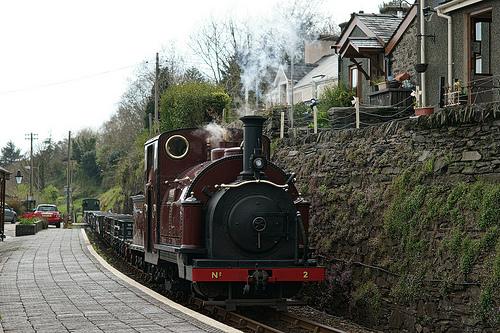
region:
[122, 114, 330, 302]
and old fashioned train engine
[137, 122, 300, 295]
the train is burgundy, black, and red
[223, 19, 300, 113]
white smoke billowing from train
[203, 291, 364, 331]
train tracks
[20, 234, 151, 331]
a stone pathway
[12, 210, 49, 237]
flowerboxes with red flowers in them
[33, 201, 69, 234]
the rear end of a red car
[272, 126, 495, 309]
a stone wall next to the train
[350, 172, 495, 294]
wall is covered in green vegetation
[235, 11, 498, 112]
houses on top of stone wall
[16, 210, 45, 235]
red flowers in planter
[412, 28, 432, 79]
hanging black flower pot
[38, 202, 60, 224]
red car on left of train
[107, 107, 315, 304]
steam locomotive engine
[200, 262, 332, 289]
red train cattle guard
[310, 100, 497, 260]
rocks embankment on right of train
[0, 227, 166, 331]
grey cobblestone street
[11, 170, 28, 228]
vintage street light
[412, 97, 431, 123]
red clay flower pot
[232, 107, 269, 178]
train smoke stack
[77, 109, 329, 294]
red and black steam engine train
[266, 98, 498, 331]
rocky embankment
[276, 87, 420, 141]
post and wire fencing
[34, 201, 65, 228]
red car parked at the roadside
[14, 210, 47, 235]
planter of red flowers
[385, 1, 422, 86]
stone facade of a house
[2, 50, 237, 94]
wires strung across the roadway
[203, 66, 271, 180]
smoke coming out of smokestack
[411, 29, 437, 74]
empty hanging plant holder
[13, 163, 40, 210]
streetlamp overhanging the road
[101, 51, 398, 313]
the vintage train is moving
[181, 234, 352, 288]
the letters n1 and 2 in gold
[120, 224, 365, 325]
gold text on the train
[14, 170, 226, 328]
the platform has paving stones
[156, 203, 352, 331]
train tracks near a wall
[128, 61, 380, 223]
steam coming from a train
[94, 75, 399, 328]
this is a vintage train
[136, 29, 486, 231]
houses overlooking a train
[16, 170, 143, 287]
red car in parking lot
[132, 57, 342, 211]
row of trees in background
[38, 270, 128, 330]
gray lines on the platform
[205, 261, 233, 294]
yellow lines on the red strip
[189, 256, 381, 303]
red strip at front of train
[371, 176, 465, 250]
green moss on side of wall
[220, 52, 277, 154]
steam coming out of train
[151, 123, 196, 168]
large silver hole in front of train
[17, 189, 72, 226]
red and white car parked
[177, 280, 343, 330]
long train tracks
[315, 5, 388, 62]
triangular roof of house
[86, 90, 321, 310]
old fashioned red and black train on track